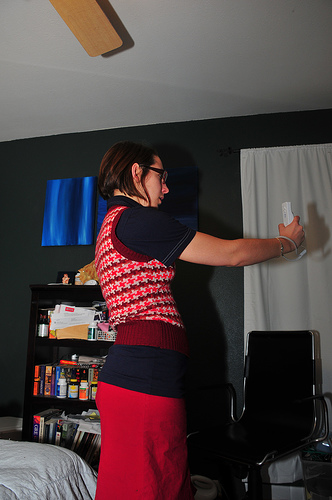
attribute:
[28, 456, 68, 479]
blanket — white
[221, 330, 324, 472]
black chair — large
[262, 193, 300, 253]
wii remote — white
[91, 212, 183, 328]
vest — red, white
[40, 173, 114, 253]
painting — blue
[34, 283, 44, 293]
shelf — black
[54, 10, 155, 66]
ceiling fan — wooden, brown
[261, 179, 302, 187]
curtains — white, cotton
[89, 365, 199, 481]
skirt — red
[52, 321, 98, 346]
object — neon, orange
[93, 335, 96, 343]
bottle — green, white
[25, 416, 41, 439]
book — red, blue, white